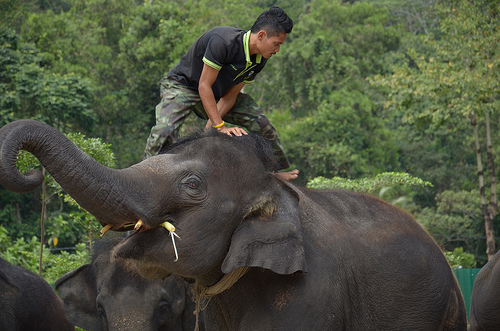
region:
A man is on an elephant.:
[1, 2, 489, 329]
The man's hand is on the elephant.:
[190, 100, 262, 147]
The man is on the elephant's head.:
[2, 3, 330, 301]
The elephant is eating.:
[91, 201, 199, 266]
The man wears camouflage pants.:
[145, 74, 294, 168]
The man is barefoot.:
[258, 156, 316, 190]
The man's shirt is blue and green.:
[169, 27, 273, 102]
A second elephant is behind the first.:
[60, 233, 200, 329]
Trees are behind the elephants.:
[0, 1, 496, 163]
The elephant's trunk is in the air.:
[0, 110, 161, 240]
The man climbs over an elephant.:
[123, 5, 353, 195]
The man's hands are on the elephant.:
[181, 97, 261, 156]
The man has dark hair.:
[237, 2, 304, 42]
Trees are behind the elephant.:
[0, 0, 499, 165]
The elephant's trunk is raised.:
[0, 107, 230, 223]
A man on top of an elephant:
[140, 0, 310, 185]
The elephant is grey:
[56, 154, 463, 329]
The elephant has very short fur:
[299, 186, 391, 203]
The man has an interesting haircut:
[246, 3, 298, 45]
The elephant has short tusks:
[93, 218, 178, 235]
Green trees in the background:
[303, 3, 471, 170]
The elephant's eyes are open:
[178, 174, 213, 193]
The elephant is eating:
[139, 228, 184, 260]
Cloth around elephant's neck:
[169, 260, 261, 305]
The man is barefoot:
[267, 162, 304, 187]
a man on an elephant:
[30, 10, 425, 325]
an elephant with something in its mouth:
[21, 100, 314, 320]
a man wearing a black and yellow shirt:
[154, 5, 384, 230]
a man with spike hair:
[126, 0, 388, 225]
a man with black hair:
[108, 17, 468, 259]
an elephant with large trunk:
[14, 60, 372, 272]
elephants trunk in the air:
[21, 67, 292, 329]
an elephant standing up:
[22, 20, 429, 323]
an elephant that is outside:
[55, 29, 435, 325]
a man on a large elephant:
[82, 17, 467, 326]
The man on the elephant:
[142, 4, 303, 183]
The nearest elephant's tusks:
[89, 214, 146, 236]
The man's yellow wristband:
[208, 115, 227, 130]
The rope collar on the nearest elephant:
[191, 261, 253, 327]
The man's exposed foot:
[269, 163, 305, 186]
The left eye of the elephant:
[181, 173, 204, 193]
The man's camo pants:
[144, 77, 291, 172]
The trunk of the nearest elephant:
[0, 116, 120, 222]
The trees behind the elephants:
[0, 0, 498, 278]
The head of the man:
[247, 3, 296, 65]